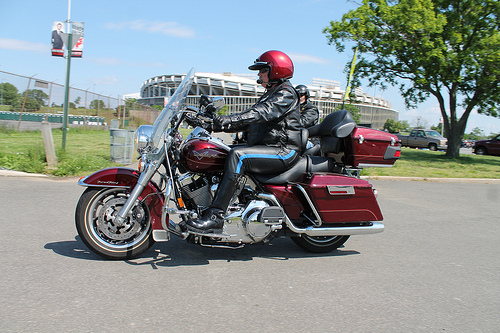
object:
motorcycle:
[70, 64, 392, 263]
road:
[0, 173, 499, 332]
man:
[178, 49, 305, 238]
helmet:
[244, 47, 297, 86]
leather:
[215, 80, 306, 178]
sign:
[65, 20, 86, 60]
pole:
[58, 0, 73, 153]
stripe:
[235, 148, 298, 174]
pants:
[180, 141, 305, 237]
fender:
[76, 165, 171, 244]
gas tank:
[178, 135, 234, 177]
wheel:
[70, 165, 169, 263]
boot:
[178, 169, 249, 236]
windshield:
[144, 62, 200, 153]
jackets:
[214, 80, 306, 154]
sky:
[0, 0, 500, 127]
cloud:
[0, 3, 215, 69]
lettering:
[70, 23, 85, 33]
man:
[50, 22, 66, 52]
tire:
[291, 219, 357, 254]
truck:
[392, 127, 451, 153]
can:
[108, 126, 139, 167]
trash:
[109, 152, 135, 166]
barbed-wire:
[0, 68, 155, 128]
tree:
[319, 0, 500, 165]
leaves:
[424, 18, 440, 28]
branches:
[387, 3, 454, 57]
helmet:
[294, 84, 312, 100]